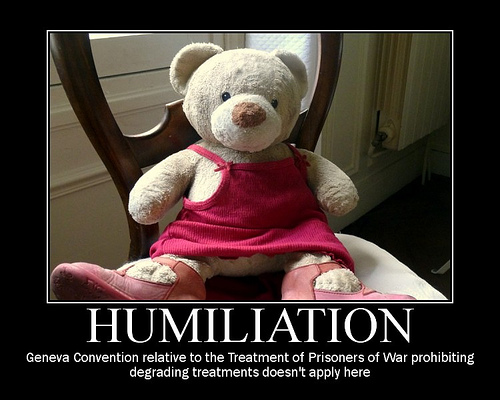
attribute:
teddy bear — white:
[135, 37, 377, 315]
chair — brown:
[347, 242, 415, 284]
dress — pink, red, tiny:
[208, 155, 305, 250]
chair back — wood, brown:
[79, 84, 142, 168]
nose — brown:
[229, 104, 268, 130]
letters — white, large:
[84, 306, 422, 345]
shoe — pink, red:
[277, 263, 419, 301]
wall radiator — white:
[368, 107, 402, 164]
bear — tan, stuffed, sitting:
[155, 39, 343, 187]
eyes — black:
[216, 87, 280, 107]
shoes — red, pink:
[39, 252, 427, 300]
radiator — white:
[370, 107, 395, 126]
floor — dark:
[403, 197, 435, 246]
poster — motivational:
[12, 8, 483, 400]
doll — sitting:
[160, 63, 305, 167]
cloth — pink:
[247, 173, 291, 211]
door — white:
[113, 36, 148, 95]